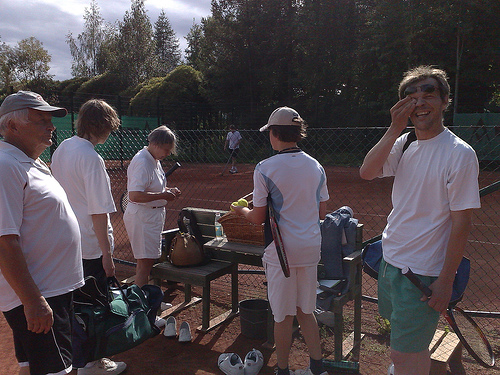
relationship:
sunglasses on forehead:
[404, 81, 442, 96] [404, 76, 441, 94]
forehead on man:
[404, 76, 441, 94] [358, 64, 483, 375]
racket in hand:
[399, 266, 496, 369] [421, 277, 456, 315]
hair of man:
[1, 108, 31, 133] [2, 90, 88, 374]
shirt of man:
[382, 127, 482, 275] [358, 64, 483, 375]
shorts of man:
[374, 254, 448, 350] [358, 64, 483, 375]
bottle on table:
[212, 211, 224, 241] [203, 225, 355, 270]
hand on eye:
[388, 95, 416, 128] [405, 95, 417, 106]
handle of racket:
[400, 266, 449, 313] [399, 266, 496, 369]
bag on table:
[166, 229, 205, 271] [203, 225, 355, 270]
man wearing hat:
[232, 105, 333, 375] [257, 104, 304, 133]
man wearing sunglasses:
[358, 64, 483, 375] [404, 81, 442, 96]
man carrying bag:
[358, 64, 483, 375] [360, 233, 471, 311]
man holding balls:
[232, 105, 333, 375] [236, 198, 249, 212]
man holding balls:
[232, 105, 333, 375] [228, 201, 237, 211]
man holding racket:
[358, 64, 483, 375] [399, 266, 496, 369]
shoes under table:
[216, 348, 266, 374] [203, 225, 355, 270]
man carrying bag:
[50, 97, 126, 374] [68, 276, 155, 364]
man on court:
[223, 122, 240, 174] [9, 152, 500, 336]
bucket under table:
[238, 296, 272, 341] [203, 225, 355, 270]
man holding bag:
[50, 97, 126, 374] [68, 276, 155, 364]